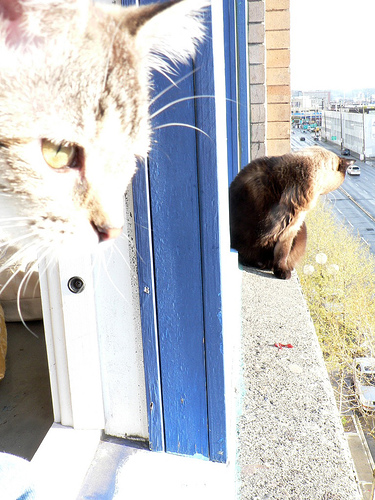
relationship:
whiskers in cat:
[2, 214, 60, 328] [230, 136, 350, 279]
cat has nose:
[0, 1, 213, 343] [90, 216, 118, 244]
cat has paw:
[244, 136, 349, 222] [275, 262, 295, 282]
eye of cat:
[2, 0, 239, 343] [37, 136, 86, 171]